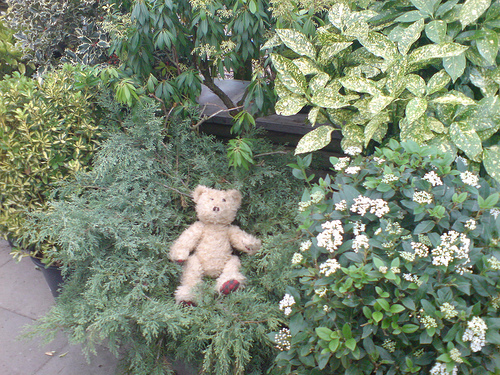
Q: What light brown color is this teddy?
A: Tan.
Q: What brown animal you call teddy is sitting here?
A: Bear.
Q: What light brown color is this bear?
A: Tan.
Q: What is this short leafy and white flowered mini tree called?
A: Bush.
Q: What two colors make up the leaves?
A: Yellow and green.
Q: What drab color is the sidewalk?
A: Grey.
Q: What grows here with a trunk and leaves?
A: Tree.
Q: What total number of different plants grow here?
A: Six.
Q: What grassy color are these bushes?
A: Green.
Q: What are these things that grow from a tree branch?
A: Leaves.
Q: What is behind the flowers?
A: Green plant.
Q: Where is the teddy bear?
A: Bush.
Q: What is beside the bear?
A: Flowers.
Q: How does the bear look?
A: Furry.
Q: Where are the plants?
A: Garden.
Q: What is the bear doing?
A: Lying.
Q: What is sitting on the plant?
A: A teddy bear.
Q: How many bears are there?
A: One.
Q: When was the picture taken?
A: During the day.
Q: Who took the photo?
A: The photographer.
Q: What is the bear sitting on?
A: A bush.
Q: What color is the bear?
A: Tan.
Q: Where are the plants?
A: By the sidewalk.